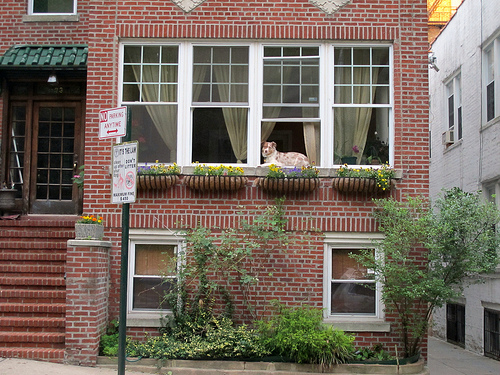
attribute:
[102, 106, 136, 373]
sign — white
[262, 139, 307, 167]
dog — brown, white, sitting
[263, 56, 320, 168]
window — white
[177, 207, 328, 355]
bushes — overgrown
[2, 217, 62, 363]
stairs — brick, red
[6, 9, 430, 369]
building — red brick, brick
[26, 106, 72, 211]
door — glass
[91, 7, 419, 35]
brick — red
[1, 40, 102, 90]
overhang — green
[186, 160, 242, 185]
flowers — yellow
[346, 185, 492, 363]
tree — tall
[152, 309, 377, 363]
flowers — green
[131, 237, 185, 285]
board — brown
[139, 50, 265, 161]
curtains — sheer